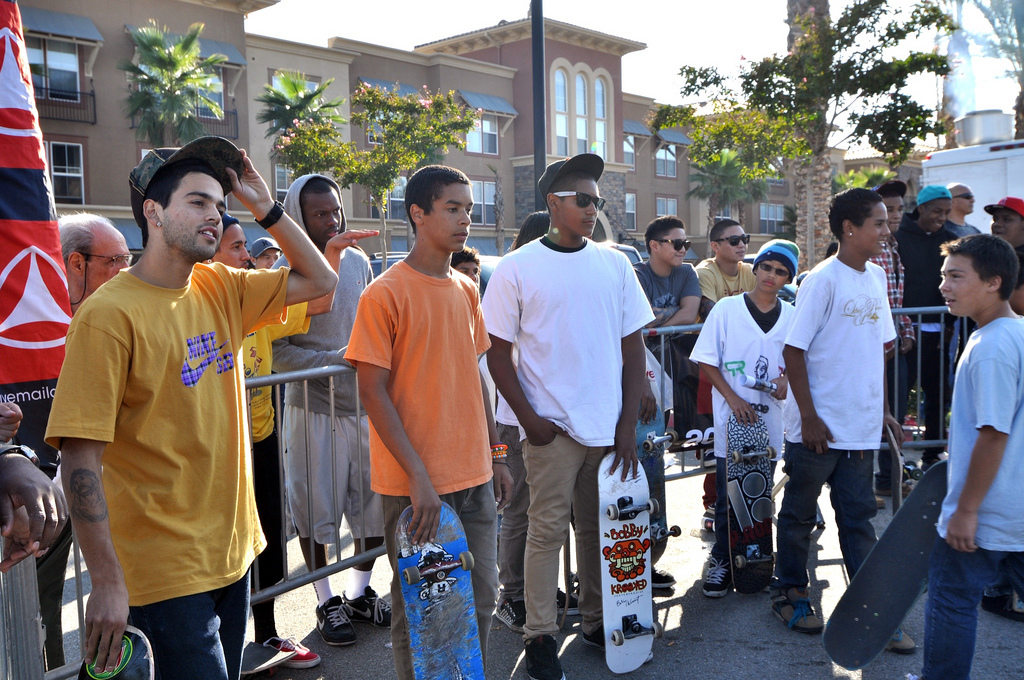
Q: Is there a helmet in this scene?
A: No, there are no helmets.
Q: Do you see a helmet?
A: No, there are no helmets.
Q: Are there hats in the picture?
A: Yes, there is a hat.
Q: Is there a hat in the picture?
A: Yes, there is a hat.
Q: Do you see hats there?
A: Yes, there is a hat.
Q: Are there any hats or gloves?
A: Yes, there is a hat.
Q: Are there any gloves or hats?
A: Yes, there is a hat.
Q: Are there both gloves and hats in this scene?
A: No, there is a hat but no gloves.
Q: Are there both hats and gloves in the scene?
A: No, there is a hat but no gloves.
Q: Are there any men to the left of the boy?
A: Yes, there is a man to the left of the boy.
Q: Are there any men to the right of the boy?
A: No, the man is to the left of the boy.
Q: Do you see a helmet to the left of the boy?
A: No, there is a man to the left of the boy.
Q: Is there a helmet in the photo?
A: No, there are no helmets.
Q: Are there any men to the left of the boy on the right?
A: Yes, there are men to the left of the boy.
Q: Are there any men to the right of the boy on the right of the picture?
A: No, the men are to the left of the boy.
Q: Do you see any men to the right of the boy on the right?
A: No, the men are to the left of the boy.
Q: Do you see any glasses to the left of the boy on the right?
A: No, there are men to the left of the boy.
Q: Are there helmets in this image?
A: No, there are no helmets.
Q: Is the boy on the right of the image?
A: Yes, the boy is on the right of the image.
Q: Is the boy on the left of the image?
A: No, the boy is on the right of the image.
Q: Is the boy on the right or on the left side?
A: The boy is on the right of the image.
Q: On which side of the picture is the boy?
A: The boy is on the right of the image.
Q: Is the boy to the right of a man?
A: Yes, the boy is to the right of a man.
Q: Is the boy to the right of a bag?
A: No, the boy is to the right of a man.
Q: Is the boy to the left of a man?
A: No, the boy is to the right of a man.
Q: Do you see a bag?
A: No, there are no bags.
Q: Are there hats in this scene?
A: Yes, there is a hat.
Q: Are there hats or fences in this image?
A: Yes, there is a hat.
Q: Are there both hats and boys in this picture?
A: Yes, there are both a hat and a boy.